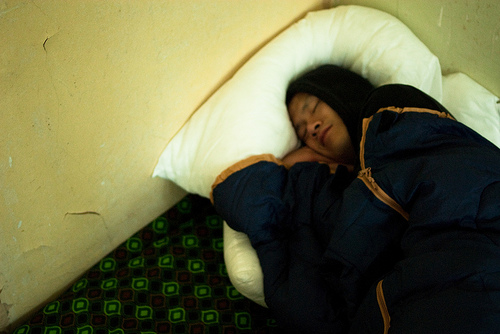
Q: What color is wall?
A: Yellow.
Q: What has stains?
A: Wall.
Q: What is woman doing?
A: Sleeping.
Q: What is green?
A: Carpet.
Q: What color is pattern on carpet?
A: Green.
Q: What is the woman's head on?
A: Pillow.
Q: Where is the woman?
A: Laying on the pillow.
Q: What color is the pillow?
A: White.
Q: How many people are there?
A: 1.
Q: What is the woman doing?
A: Sleeping.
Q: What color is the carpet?
A: Brown and green.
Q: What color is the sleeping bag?
A: Blue.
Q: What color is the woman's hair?
A: Black.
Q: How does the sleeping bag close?
A: Zips.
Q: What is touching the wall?
A: Pillow.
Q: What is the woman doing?
A: Sleeping.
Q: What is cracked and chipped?
A: Paint.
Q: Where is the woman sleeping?
A: In a sleeping bag.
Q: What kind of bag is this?
A: Sleeping bag.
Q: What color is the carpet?
A: Green.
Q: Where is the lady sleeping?
A: In a corner.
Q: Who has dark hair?
A: The lady.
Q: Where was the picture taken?
A: At a house.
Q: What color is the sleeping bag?
A: Blue.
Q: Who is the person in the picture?
A: A sleeping man.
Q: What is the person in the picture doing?
A: Sleeping.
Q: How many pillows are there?
A: Two.